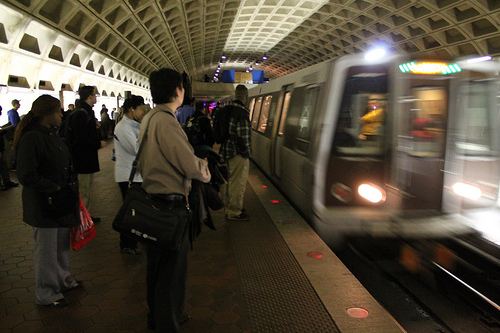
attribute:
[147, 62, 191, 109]
hair — short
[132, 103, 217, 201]
shirt — brown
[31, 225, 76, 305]
pants — gray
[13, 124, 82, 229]
coat — black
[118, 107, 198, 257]
bag — black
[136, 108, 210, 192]
coat — tan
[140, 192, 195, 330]
pants — black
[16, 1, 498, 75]
ceiling — domed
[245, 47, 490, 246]
train — silver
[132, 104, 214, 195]
sweater — tan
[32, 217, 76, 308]
pants — gray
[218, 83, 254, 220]
man — dark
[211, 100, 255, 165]
shirt — plaid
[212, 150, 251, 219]
pants — tan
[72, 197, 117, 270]
plastic — red, shopping bag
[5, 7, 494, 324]
station — train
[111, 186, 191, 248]
bag — black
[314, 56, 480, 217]
train — long, silver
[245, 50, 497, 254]
lights — white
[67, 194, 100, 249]
bag — red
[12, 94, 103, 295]
woman — black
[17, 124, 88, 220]
coat — black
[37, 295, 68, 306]
shoe — black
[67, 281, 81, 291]
shoe — black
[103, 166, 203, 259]
bag — black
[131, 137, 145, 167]
strap — long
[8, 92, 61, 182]
hair — black, long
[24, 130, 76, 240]
jacket — black